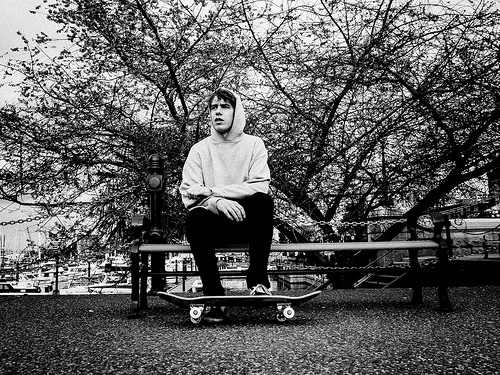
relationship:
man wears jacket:
[166, 70, 291, 287] [178, 87, 272, 213]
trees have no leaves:
[274, 32, 470, 176] [29, 6, 70, 26]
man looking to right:
[166, 70, 291, 287] [316, 156, 355, 171]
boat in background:
[8, 266, 49, 297] [16, 238, 50, 260]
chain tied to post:
[5, 214, 49, 230] [142, 147, 171, 226]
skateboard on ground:
[154, 283, 324, 308] [306, 330, 408, 360]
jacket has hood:
[192, 139, 249, 169] [235, 89, 246, 130]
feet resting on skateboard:
[246, 285, 274, 302] [154, 283, 324, 308]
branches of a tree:
[345, 48, 415, 103] [67, 33, 148, 99]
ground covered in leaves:
[306, 330, 408, 360] [29, 6, 70, 26]